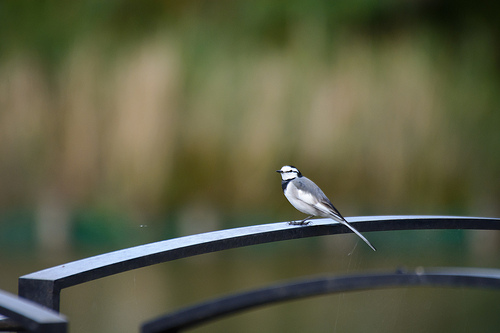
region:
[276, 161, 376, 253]
Small gray and white bird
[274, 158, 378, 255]
Bird with gray and white feathers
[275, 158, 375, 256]
Bird perched on a rail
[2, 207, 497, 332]
Black metal rails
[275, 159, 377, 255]
Bird sitting on a metal rail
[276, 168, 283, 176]
Small black beak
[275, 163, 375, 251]
Bird standing on a rail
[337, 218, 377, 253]
White and black bird tail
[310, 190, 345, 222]
Feathers on a bird's wings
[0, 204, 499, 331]
Black metal railings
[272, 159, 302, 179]
head of a bird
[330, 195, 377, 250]
tail of a bird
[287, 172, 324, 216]
body of a bird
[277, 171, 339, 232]
a body of a bird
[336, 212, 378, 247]
a tail of a bird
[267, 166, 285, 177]
peck of a bird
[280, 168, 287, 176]
an eye of a bird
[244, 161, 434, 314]
a bird on a metal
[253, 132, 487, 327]
a small bird on metal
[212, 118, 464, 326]
a bird standing outside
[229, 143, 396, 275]
a small bird standing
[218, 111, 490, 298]
a small bird standing outside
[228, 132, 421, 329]
a small bird that is outside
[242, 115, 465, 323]
a black metal piece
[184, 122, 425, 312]
a small bird on a metal piece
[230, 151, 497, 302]
a bird standing in daylight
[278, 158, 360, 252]
Bird standing on a fence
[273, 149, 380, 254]
Bird standing on a fence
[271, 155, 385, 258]
Bird standing on a fence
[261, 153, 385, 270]
Bird standing on a fence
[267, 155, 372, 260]
Bird standing on a fence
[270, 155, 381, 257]
Bird standing on a fence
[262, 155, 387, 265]
Bird standing on a fence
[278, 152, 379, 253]
Bird standing on a fence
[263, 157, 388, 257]
Bird standing on a fence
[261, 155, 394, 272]
Bird standing on a fence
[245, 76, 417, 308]
this is a small bird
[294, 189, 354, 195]
the bird is black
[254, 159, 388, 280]
the bird is grey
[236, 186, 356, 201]
the bird is white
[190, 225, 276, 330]
this is a fence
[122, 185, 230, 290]
the fence is metal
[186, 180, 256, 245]
the fence is dark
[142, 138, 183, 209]
the background is blurry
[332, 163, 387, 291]
this is the tail